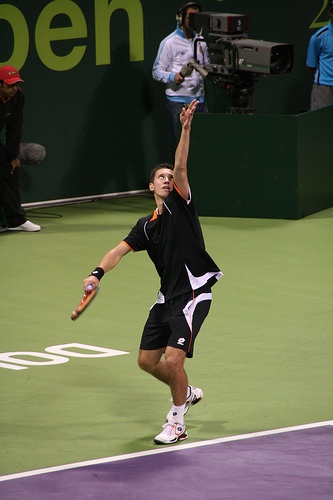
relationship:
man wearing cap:
[0, 63, 42, 232] [0, 63, 25, 86]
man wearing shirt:
[302, 5, 331, 110] [305, 19, 332, 88]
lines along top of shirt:
[143, 181, 192, 243] [122, 175, 222, 303]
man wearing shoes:
[70, 98, 223, 444] [153, 382, 205, 448]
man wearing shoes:
[0, 63, 42, 232] [3, 219, 39, 235]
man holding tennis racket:
[70, 98, 223, 444] [68, 283, 99, 321]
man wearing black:
[0, 63, 42, 232] [1, 89, 28, 229]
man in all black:
[0, 63, 42, 232] [1, 89, 28, 229]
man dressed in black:
[0, 63, 42, 232] [1, 89, 28, 229]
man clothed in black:
[0, 63, 42, 232] [1, 89, 28, 229]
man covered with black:
[0, 63, 42, 232] [1, 89, 28, 229]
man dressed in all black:
[0, 63, 42, 232] [1, 89, 28, 229]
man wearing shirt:
[70, 98, 223, 444] [122, 175, 222, 303]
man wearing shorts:
[70, 98, 223, 444] [137, 284, 212, 357]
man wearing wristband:
[70, 98, 223, 444] [89, 266, 104, 280]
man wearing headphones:
[150, 1, 211, 152] [174, 1, 202, 31]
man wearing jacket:
[150, 1, 211, 152] [150, 25, 210, 106]